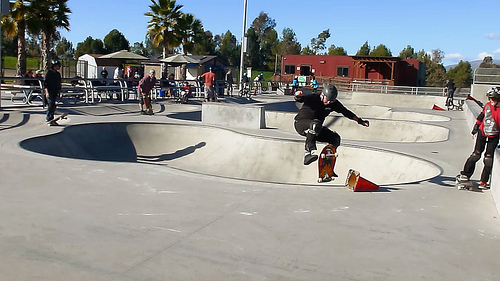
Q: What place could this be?
A: It is a park.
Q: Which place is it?
A: It is a park.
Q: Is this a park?
A: Yes, it is a park.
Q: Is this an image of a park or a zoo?
A: It is showing a park.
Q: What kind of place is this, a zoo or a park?
A: It is a park.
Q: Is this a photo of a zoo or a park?
A: It is showing a park.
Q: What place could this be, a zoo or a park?
A: It is a park.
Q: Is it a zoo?
A: No, it is a park.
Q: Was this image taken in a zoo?
A: No, the picture was taken in a park.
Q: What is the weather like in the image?
A: It is clear.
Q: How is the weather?
A: It is clear.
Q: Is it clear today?
A: Yes, it is clear.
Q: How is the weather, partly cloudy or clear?
A: It is clear.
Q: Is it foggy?
A: No, it is clear.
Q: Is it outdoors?
A: Yes, it is outdoors.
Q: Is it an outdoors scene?
A: Yes, it is outdoors.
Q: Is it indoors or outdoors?
A: It is outdoors.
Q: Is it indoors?
A: No, it is outdoors.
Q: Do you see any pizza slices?
A: No, there are no pizza slices.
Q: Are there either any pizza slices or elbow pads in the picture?
A: No, there are no pizza slices or elbow pads.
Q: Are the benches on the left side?
A: Yes, the benches are on the left of the image.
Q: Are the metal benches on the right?
A: No, the benches are on the left of the image.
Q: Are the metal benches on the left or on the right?
A: The benches are on the left of the image.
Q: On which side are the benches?
A: The benches are on the left of the image.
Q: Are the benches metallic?
A: Yes, the benches are metallic.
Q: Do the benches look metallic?
A: Yes, the benches are metallic.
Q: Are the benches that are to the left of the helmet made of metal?
A: Yes, the benches are made of metal.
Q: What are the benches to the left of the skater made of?
A: The benches are made of metal.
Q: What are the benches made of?
A: The benches are made of metal.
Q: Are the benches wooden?
A: No, the benches are metallic.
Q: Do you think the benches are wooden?
A: No, the benches are metallic.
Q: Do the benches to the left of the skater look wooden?
A: No, the benches are metallic.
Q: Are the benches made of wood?
A: No, the benches are made of metal.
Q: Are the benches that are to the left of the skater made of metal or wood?
A: The benches are made of metal.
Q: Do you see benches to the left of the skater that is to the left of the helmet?
A: Yes, there are benches to the left of the skater.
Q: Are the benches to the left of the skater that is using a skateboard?
A: Yes, the benches are to the left of the skater.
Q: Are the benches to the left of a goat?
A: No, the benches are to the left of the skater.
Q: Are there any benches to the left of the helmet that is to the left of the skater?
A: Yes, there are benches to the left of the helmet.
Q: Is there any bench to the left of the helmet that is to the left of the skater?
A: Yes, there are benches to the left of the helmet.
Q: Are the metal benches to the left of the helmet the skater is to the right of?
A: Yes, the benches are to the left of the helmet.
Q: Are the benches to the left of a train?
A: No, the benches are to the left of the helmet.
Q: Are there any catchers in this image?
A: No, there are no catchers.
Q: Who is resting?
A: The skater is resting.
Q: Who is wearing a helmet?
A: The skater is wearing a helmet.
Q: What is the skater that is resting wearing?
A: The skater is wearing a helmet.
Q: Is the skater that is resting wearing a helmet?
A: Yes, the skater is wearing a helmet.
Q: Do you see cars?
A: No, there are no cars.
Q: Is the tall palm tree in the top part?
A: Yes, the palm is in the top of the image.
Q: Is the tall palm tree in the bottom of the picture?
A: No, the palm is in the top of the image.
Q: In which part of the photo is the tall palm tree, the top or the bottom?
A: The palm is in the top of the image.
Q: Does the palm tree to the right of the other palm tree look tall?
A: Yes, the palm tree is tall.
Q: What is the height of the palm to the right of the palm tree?
A: The palm is tall.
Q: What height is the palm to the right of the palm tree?
A: The palm is tall.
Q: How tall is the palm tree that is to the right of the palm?
A: The palm tree is tall.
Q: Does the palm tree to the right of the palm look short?
A: No, the palm is tall.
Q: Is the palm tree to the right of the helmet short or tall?
A: The palm tree is tall.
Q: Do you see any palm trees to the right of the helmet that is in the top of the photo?
A: Yes, there is a palm tree to the right of the helmet.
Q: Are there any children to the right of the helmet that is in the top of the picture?
A: No, there is a palm tree to the right of the helmet.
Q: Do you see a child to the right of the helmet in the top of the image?
A: No, there is a palm tree to the right of the helmet.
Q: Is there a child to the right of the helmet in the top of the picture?
A: No, there is a palm tree to the right of the helmet.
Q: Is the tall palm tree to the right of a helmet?
A: Yes, the palm tree is to the right of a helmet.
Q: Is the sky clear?
A: Yes, the sky is clear.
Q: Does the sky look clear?
A: Yes, the sky is clear.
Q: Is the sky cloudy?
A: No, the sky is clear.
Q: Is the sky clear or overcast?
A: The sky is clear.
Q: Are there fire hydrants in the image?
A: No, there are no fire hydrants.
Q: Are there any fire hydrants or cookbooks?
A: No, there are no fire hydrants or cookbooks.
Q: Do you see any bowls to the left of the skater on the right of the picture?
A: Yes, there is a bowl to the left of the skater.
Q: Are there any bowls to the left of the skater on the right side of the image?
A: Yes, there is a bowl to the left of the skater.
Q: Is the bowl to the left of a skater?
A: Yes, the bowl is to the left of a skater.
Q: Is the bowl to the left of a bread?
A: No, the bowl is to the left of a skater.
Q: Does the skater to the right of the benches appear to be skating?
A: Yes, the skater is skating.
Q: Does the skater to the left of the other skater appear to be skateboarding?
A: No, the skater is skating.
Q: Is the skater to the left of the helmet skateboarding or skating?
A: The skater is skating.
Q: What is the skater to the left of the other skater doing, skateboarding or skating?
A: The skater is skating.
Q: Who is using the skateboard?
A: The skater is using the skateboard.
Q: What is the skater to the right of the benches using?
A: The skater is using a skateboard.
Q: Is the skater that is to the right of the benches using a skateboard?
A: Yes, the skater is using a skateboard.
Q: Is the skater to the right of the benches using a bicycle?
A: No, the skater is using a skateboard.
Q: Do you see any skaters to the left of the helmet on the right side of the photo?
A: Yes, there is a skater to the left of the helmet.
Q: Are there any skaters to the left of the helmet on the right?
A: Yes, there is a skater to the left of the helmet.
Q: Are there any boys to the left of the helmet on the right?
A: No, there is a skater to the left of the helmet.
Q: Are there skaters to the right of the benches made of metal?
A: Yes, there is a skater to the right of the benches.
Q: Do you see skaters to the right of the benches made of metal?
A: Yes, there is a skater to the right of the benches.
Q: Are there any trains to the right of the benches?
A: No, there is a skater to the right of the benches.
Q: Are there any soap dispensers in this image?
A: No, there are no soap dispensers.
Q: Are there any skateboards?
A: Yes, there is a skateboard.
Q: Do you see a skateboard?
A: Yes, there is a skateboard.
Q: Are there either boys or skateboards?
A: Yes, there is a skateboard.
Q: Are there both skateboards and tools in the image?
A: No, there is a skateboard but no tools.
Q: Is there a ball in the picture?
A: No, there are no balls.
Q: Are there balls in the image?
A: No, there are no balls.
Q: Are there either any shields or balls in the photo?
A: No, there are no balls or shields.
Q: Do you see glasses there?
A: No, there are no glasses.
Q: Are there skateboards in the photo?
A: Yes, there is a skateboard.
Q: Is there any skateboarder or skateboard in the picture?
A: Yes, there is a skateboard.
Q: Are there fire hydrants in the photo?
A: No, there are no fire hydrants.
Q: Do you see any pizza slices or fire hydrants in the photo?
A: No, there are no fire hydrants or pizza slices.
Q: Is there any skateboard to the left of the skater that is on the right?
A: Yes, there is a skateboard to the left of the skater.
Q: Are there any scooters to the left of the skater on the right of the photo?
A: No, there is a skateboard to the left of the skater.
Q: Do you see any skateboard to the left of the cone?
A: Yes, there is a skateboard to the left of the cone.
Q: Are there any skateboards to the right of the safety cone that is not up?
A: No, the skateboard is to the left of the cone.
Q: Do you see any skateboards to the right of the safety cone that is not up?
A: No, the skateboard is to the left of the cone.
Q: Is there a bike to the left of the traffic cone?
A: No, there is a skateboard to the left of the traffic cone.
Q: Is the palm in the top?
A: Yes, the palm is in the top of the image.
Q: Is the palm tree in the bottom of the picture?
A: No, the palm tree is in the top of the image.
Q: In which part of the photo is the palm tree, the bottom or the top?
A: The palm tree is in the top of the image.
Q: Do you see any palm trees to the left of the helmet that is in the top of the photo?
A: Yes, there is a palm tree to the left of the helmet.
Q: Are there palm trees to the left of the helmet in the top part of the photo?
A: Yes, there is a palm tree to the left of the helmet.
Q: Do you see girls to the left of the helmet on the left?
A: No, there is a palm tree to the left of the helmet.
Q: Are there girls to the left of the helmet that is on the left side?
A: No, there is a palm tree to the left of the helmet.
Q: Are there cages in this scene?
A: No, there are no cages.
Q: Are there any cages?
A: No, there are no cages.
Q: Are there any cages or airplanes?
A: No, there are no cages or airplanes.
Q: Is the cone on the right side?
A: Yes, the cone is on the right of the image.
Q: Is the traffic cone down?
A: Yes, the traffic cone is down.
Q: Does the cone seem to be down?
A: Yes, the cone is down.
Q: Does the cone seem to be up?
A: No, the cone is down.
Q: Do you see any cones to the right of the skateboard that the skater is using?
A: Yes, there is a cone to the right of the skateboard.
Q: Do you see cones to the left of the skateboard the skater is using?
A: No, the cone is to the right of the skateboard.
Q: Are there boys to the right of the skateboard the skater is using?
A: No, there is a cone to the right of the skateboard.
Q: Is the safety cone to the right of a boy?
A: No, the safety cone is to the right of the skateboard.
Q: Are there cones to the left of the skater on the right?
A: Yes, there is a cone to the left of the skater.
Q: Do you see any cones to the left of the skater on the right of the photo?
A: Yes, there is a cone to the left of the skater.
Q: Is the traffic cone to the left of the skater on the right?
A: Yes, the traffic cone is to the left of the skater.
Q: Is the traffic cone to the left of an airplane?
A: No, the traffic cone is to the left of the skater.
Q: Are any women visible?
A: No, there are no women.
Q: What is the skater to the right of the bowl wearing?
A: The skater is wearing a helmet.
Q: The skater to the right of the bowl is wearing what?
A: The skater is wearing a helmet.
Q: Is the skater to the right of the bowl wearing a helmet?
A: Yes, the skater is wearing a helmet.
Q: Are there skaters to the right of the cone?
A: Yes, there is a skater to the right of the cone.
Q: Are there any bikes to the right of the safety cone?
A: No, there is a skater to the right of the safety cone.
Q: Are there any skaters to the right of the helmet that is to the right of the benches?
A: Yes, there is a skater to the right of the helmet.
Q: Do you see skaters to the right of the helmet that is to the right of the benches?
A: Yes, there is a skater to the right of the helmet.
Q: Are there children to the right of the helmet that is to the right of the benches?
A: No, there is a skater to the right of the helmet.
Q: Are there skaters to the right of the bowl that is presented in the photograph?
A: Yes, there is a skater to the right of the bowl.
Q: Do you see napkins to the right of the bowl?
A: No, there is a skater to the right of the bowl.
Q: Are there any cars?
A: No, there are no cars.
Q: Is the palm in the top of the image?
A: Yes, the palm is in the top of the image.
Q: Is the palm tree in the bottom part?
A: No, the palm tree is in the top of the image.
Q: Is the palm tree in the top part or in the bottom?
A: The palm tree is in the top of the image.